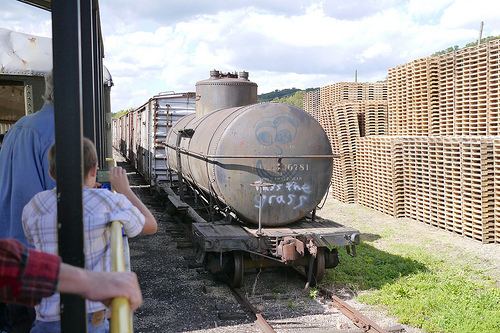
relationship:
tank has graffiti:
[146, 44, 356, 274] [249, 111, 306, 183]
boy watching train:
[20, 136, 158, 333] [109, 63, 373, 291]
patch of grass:
[388, 266, 433, 305] [390, 246, 466, 315]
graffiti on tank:
[254, 166, 312, 226] [162, 69, 334, 222]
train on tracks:
[109, 63, 373, 291] [221, 276, 388, 331]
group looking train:
[2, 65, 143, 332] [109, 63, 373, 291]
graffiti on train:
[233, 107, 308, 209] [109, 63, 373, 291]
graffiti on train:
[254, 180, 310, 210] [159, 53, 360, 308]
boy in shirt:
[20, 136, 157, 330] [20, 185, 145, 322]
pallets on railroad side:
[302, 35, 497, 245] [363, 244, 498, 291]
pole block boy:
[56, 0, 88, 330] [20, 136, 158, 333]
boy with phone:
[20, 136, 158, 333] [96, 169, 112, 182]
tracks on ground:
[221, 276, 388, 331] [229, 260, 372, 330]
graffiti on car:
[254, 180, 310, 210] [158, 63, 360, 257]